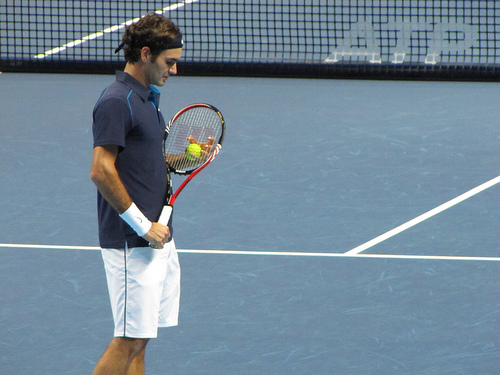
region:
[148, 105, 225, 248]
a man's tennis racket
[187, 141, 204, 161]
a man's tennis ball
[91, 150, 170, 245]
a man's right arm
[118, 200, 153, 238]
a man's wrist band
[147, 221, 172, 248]
a man's right hand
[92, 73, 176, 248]
a man's tennis shirt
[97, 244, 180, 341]
a man's tennis shorts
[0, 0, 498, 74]
a black tennis net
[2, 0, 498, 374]
a green painted tennis court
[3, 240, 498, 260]
painted line on a tennis court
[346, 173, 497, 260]
white line on tennis court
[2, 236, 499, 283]
white line on tennis court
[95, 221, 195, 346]
pair of white shorts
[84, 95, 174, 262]
arm of a person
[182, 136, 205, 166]
bright green tennis ball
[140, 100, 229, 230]
tennis racket with white handle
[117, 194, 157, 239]
large white wrist band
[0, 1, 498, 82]
black net on tennis court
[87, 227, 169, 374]
leg of a person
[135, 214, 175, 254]
hand of a person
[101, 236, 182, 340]
men's white tennis shorts with thin stripe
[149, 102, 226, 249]
tennis racket and ball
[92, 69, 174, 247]
navy blue polo shirt with light blue details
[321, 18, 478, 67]
sign reading ATP built in to tennis net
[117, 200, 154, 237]
white wristband with small design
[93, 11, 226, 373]
man holding tennis racket and ball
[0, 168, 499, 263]
white lines on tennis court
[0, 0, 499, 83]
tennis net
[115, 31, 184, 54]
black headband with white design on front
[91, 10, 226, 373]
man wearing blue polo shirt and white shorts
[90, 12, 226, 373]
the man playing tennis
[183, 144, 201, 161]
the tennis ball in the man's hand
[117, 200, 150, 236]
the white band on the man's arm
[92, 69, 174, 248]
the blue shirt on the man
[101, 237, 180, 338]
the white shorts on the man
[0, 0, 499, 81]
the net on the tennis court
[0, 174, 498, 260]
the white lines on the court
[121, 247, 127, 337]
the stripe on the side of the shorts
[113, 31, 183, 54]
the fabric on the man's head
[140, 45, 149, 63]
the ear on the man's head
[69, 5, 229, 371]
a man standing on tennis court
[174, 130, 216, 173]
hand holding a ball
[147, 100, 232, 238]
tennis racket is color black, red and white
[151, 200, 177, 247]
handle of racket is white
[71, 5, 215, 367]
tennis player wears a blue top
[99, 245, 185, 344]
a white short with a blue stripe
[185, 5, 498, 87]
tennis net is color black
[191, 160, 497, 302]
lines of tennis court are white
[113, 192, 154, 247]
a white wristband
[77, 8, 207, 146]
tennis player wears a headband